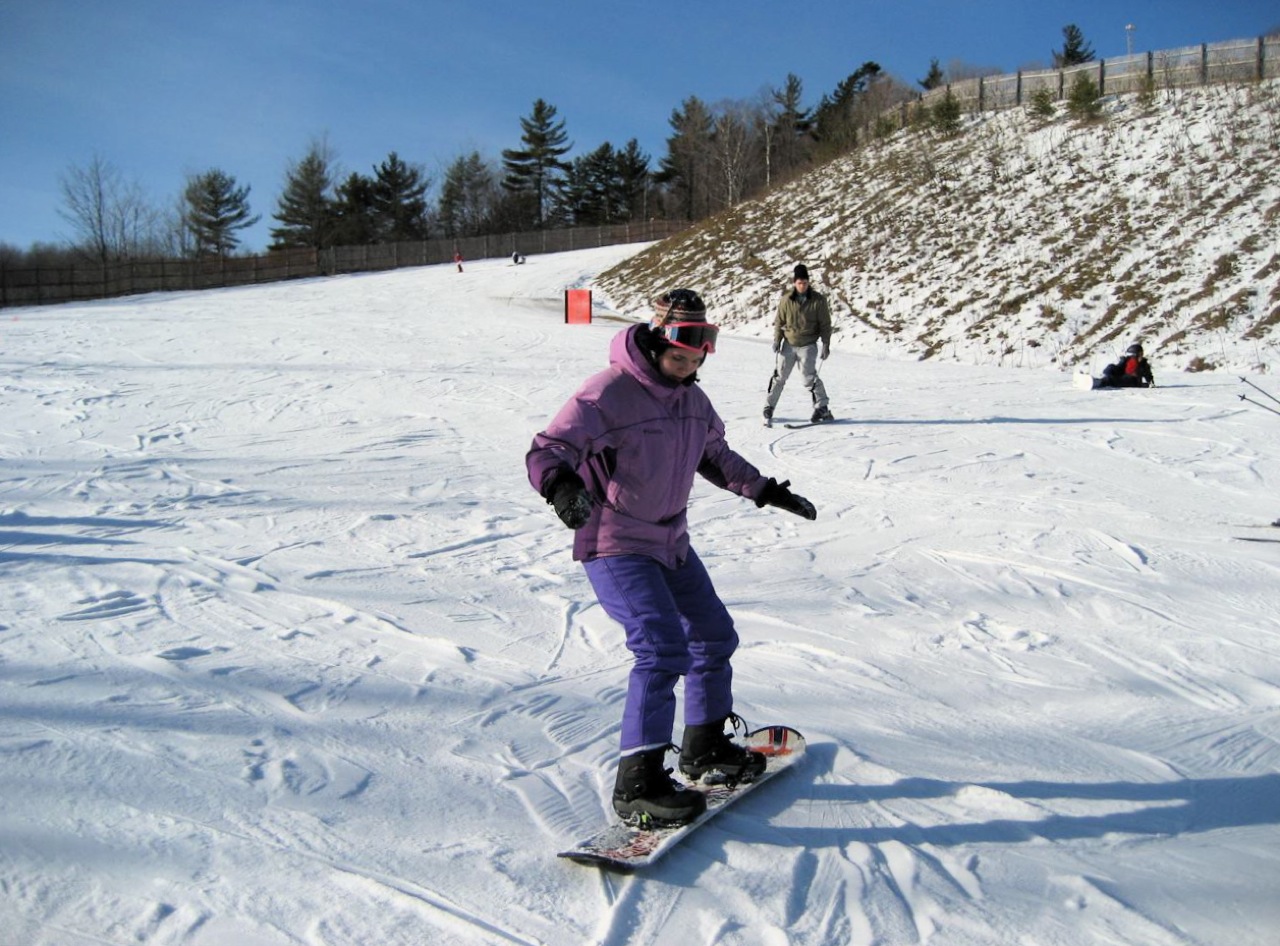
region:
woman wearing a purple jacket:
[494, 368, 748, 543]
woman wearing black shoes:
[587, 708, 771, 837]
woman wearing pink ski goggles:
[639, 306, 728, 359]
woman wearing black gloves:
[527, 463, 601, 539]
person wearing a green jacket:
[759, 284, 828, 346]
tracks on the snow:
[99, 492, 483, 850]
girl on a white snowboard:
[524, 287, 814, 881]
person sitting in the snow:
[1071, 338, 1153, 396]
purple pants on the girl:
[581, 541, 738, 767]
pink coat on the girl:
[528, 329, 778, 564]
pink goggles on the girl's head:
[643, 315, 719, 351]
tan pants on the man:
[760, 344, 833, 411]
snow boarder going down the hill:
[521, 280, 817, 881]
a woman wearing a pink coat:
[524, 285, 823, 568]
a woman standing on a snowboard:
[522, 289, 799, 865]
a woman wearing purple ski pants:
[521, 295, 756, 748]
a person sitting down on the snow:
[1097, 339, 1162, 404]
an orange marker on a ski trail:
[563, 285, 594, 317]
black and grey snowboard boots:
[619, 712, 765, 829]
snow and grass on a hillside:
[583, 92, 1270, 364]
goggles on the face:
[655, 317, 729, 353]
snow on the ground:
[913, 672, 1185, 944]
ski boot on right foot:
[602, 743, 704, 828]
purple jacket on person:
[525, 328, 784, 598]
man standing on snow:
[752, 255, 847, 430]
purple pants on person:
[567, 535, 746, 743]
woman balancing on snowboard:
[506, 281, 857, 827]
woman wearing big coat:
[519, 308, 793, 578]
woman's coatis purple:
[514, 310, 801, 595]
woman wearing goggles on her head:
[643, 308, 723, 361]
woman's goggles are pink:
[643, 310, 732, 368]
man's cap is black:
[784, 257, 818, 286]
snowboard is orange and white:
[559, 705, 831, 875]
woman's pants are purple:
[574, 526, 756, 765]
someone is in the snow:
[522, 293, 814, 878]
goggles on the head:
[672, 319, 719, 355]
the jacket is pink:
[537, 319, 774, 556]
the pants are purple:
[581, 542, 734, 761]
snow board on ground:
[563, 721, 804, 865]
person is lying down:
[1100, 346, 1151, 391]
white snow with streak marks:
[26, 516, 254, 686]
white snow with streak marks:
[860, 735, 1136, 914]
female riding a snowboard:
[517, 281, 816, 878]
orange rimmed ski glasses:
[649, 315, 720, 357]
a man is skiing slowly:
[755, 259, 839, 436]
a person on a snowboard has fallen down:
[1072, 339, 1157, 395]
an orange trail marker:
[558, 281, 596, 332]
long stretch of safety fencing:
[4, 220, 662, 305]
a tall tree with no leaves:
[48, 149, 139, 289]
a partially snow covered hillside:
[591, 100, 1271, 368]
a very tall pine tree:
[498, 96, 578, 234]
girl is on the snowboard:
[516, 282, 819, 826]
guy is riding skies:
[757, 262, 837, 430]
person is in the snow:
[450, 231, 468, 273]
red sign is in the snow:
[562, 284, 596, 331]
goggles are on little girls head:
[637, 315, 721, 351]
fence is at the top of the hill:
[853, 35, 1279, 146]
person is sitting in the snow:
[1092, 344, 1154, 391]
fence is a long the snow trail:
[0, 214, 693, 303]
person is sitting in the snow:
[511, 245, 527, 263]